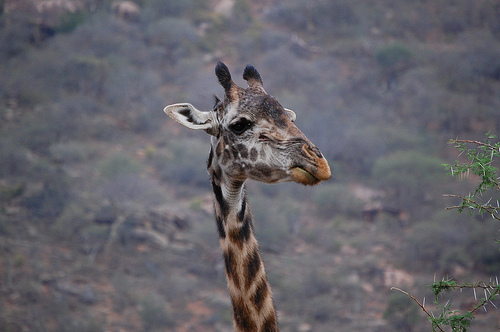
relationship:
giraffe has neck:
[163, 54, 350, 329] [208, 179, 297, 328]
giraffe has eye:
[163, 54, 350, 329] [227, 116, 255, 136]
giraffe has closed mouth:
[163, 54, 350, 329] [288, 156, 332, 188]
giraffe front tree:
[163, 54, 350, 329] [429, 86, 498, 323]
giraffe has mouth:
[163, 54, 350, 329] [293, 157, 333, 187]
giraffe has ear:
[163, 54, 350, 329] [152, 100, 224, 134]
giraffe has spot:
[163, 54, 350, 329] [236, 239, 266, 295]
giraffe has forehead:
[163, 54, 350, 329] [219, 92, 275, 109]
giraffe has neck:
[163, 54, 350, 329] [188, 200, 295, 317]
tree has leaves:
[426, 91, 497, 331] [442, 127, 499, 198]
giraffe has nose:
[163, 54, 350, 329] [297, 136, 334, 195]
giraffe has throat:
[163, 54, 350, 329] [204, 181, 293, 331]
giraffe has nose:
[163, 54, 350, 329] [293, 140, 335, 190]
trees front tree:
[408, 67, 498, 330] [422, 113, 482, 330]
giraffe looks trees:
[163, 54, 350, 329] [408, 67, 498, 330]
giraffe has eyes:
[163, 54, 350, 329] [223, 107, 263, 139]